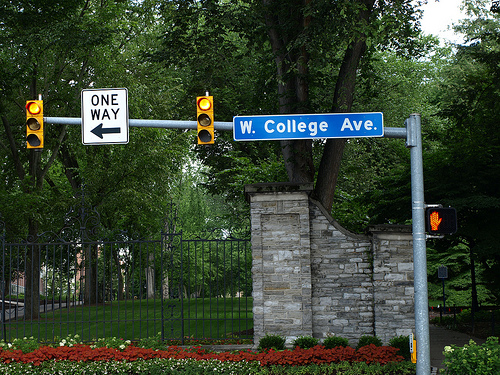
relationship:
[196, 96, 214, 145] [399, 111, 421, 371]
light is in front of bus stop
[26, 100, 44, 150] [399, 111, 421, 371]
light is in front of bus stop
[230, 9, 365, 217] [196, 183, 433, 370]
tree behind wall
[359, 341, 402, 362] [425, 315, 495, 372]
tree stump on street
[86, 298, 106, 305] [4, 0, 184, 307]
stump on tree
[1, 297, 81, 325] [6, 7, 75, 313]
street on tree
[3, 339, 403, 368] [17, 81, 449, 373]
red flowers behind light post